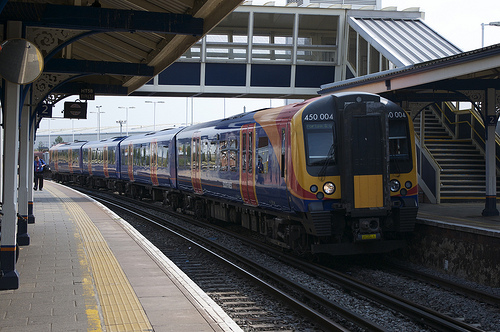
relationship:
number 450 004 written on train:
[300, 112, 335, 123] [49, 87, 421, 268]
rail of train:
[381, 254, 500, 307] [49, 87, 421, 268]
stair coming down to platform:
[419, 138, 477, 147] [412, 202, 499, 235]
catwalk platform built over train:
[134, 3, 344, 96] [49, 87, 421, 268]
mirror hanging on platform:
[2, 35, 46, 85] [0, 1, 244, 332]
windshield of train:
[303, 120, 339, 175] [49, 87, 421, 268]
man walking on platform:
[32, 153, 48, 191] [0, 1, 244, 332]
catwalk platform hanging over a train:
[134, 3, 344, 96] [49, 87, 421, 268]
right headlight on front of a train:
[309, 183, 319, 194] [49, 87, 421, 268]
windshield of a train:
[385, 117, 411, 168] [49, 87, 421, 268]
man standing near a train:
[32, 153, 48, 191] [49, 87, 421, 268]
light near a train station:
[479, 15, 499, 50] [1, 0, 500, 331]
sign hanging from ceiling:
[62, 100, 89, 121] [0, 0, 245, 97]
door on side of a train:
[238, 121, 263, 210] [49, 87, 421, 268]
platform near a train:
[412, 202, 499, 235] [49, 87, 421, 268]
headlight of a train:
[390, 180, 403, 194] [49, 87, 421, 268]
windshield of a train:
[303, 120, 339, 175] [49, 87, 421, 268]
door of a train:
[187, 128, 207, 197] [49, 87, 421, 268]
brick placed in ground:
[29, 314, 82, 324] [0, 175, 244, 331]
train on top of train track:
[49, 87, 421, 268] [42, 165, 486, 331]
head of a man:
[33, 150, 41, 161] [32, 153, 48, 191]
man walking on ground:
[32, 153, 48, 191] [0, 175, 244, 331]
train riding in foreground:
[49, 87, 421, 268] [0, 91, 499, 331]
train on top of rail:
[49, 87, 421, 268] [381, 254, 500, 307]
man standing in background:
[32, 153, 48, 191] [2, 0, 499, 193]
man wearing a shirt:
[32, 153, 48, 191] [34, 155, 50, 174]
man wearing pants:
[32, 153, 48, 191] [34, 168, 45, 194]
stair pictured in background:
[419, 138, 477, 147] [2, 0, 499, 193]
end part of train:
[287, 90, 425, 261] [49, 87, 421, 268]